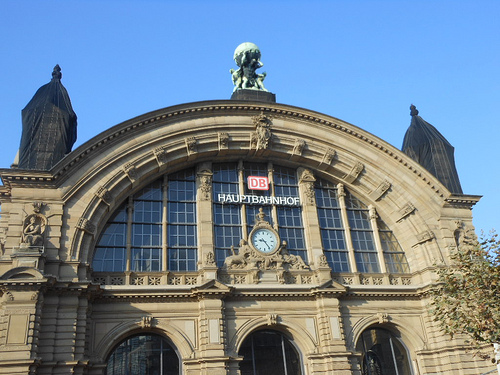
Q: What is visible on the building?
A: A clock.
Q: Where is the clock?
A: On the building.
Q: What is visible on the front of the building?
A: The clock.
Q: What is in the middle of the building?
A: A clock.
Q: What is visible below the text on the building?
A: A clock.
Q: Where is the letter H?
A: On a beautiful old building.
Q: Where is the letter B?
A: On a beautiful old building.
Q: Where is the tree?
A: Outside a building.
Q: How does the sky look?
A: Clear.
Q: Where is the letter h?
A: On the building.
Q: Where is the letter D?
A: On the building.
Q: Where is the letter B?
A: On the building.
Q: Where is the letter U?
A: On the building.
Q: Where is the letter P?
A: On the building.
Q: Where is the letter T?
A: On the building.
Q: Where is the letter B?
A: On the building.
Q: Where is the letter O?
A: On the building.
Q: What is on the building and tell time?
A: Clock.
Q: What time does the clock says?
A: 9:25.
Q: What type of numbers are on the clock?
A: Roman.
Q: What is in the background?
A: The sky.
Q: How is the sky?
A: Clear and blue.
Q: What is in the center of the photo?
A: A building.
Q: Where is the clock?
A: In front of the building.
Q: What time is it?
A: 9:25.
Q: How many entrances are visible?
A: Three.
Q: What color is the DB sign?
A: Red and white.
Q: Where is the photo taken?
A: Museum.